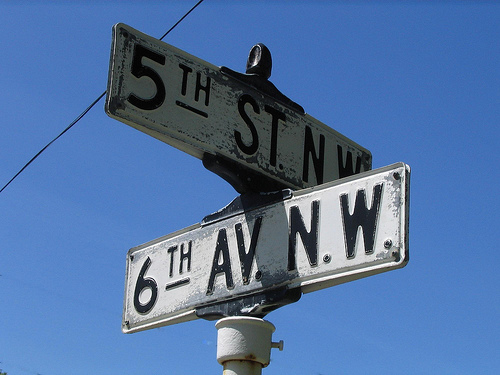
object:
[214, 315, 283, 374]
pole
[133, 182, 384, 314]
letter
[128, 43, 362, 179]
letter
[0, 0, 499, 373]
background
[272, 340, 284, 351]
screw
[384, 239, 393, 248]
bolts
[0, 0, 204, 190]
power line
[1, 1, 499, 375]
sky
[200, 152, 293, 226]
brackets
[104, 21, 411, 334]
sign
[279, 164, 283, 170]
nail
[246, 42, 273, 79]
cap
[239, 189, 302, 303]
shadow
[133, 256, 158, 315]
number 6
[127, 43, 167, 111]
number 5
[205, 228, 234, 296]
letter a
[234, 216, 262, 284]
letter v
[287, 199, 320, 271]
letter n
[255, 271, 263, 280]
dot